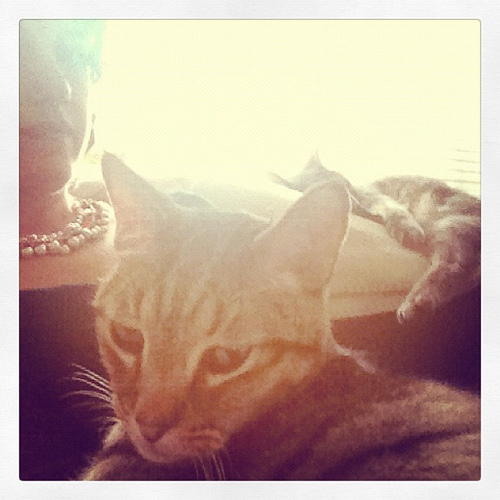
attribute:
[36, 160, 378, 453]
cat — gray, white, striped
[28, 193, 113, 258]
necklace — pearl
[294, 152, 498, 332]
cat — laying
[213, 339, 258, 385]
eye — staring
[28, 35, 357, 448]
lady — holding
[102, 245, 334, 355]
forehead — creased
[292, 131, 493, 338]
cat — sleeping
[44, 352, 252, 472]
whiskers — white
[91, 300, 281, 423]
cat — looking at the camera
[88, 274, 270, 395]
cat eyes — green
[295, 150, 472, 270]
cat — sleeping